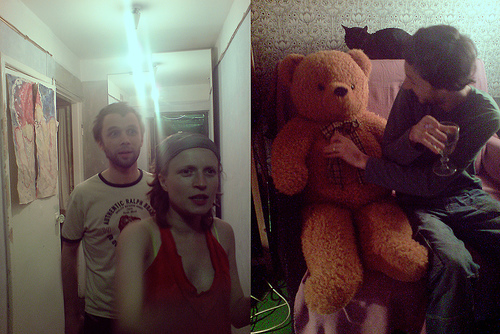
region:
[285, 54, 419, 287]
huge teddy bear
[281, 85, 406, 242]
teddy bear sitting on the furniture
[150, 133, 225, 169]
woman has a bandana on her head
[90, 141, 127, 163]
man has a beard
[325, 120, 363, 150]
bear is wearing a bow tie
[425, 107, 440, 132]
man is holding a cigarette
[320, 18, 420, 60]
cat on the back of the furniture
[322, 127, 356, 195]
man touching the bear's bow tie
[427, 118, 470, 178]
man holding a glass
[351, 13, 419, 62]
cat is black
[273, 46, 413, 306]
large brown fluffy bear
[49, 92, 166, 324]
man wearing a white shirt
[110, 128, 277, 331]
woman wearing red shirt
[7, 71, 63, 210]
painting hanging on the wall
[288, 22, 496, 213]
man sitting next to teddy bear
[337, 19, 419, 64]
small black cat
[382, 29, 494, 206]
man holding a cup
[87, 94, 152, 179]
man with short hair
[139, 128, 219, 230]
woman with grown hair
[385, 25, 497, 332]
man wearing long pants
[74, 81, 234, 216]
These people look surprised.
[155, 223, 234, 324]
The lady has a red tank top.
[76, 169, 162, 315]
The man has a white shirt with black trim.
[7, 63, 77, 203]
This is strange painting.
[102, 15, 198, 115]
The hall light is bright.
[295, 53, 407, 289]
This is a teddy bear.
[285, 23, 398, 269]
The teddy bear is large.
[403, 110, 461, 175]
This man has a wine glass.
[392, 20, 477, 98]
The man has shaggy hair.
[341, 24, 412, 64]
This is a black cat.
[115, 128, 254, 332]
Woman in a red shirt and bandana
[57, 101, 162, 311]
Man in a white shirt with logo on front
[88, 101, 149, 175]
Man with slight scruff facial hair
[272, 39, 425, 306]
Large teddy bear on a couch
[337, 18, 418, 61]
Black cat sitting on top of couch back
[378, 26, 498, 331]
Man touching a teddy bear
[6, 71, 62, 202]
Painted picture hanging on wall in background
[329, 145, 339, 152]
Gold ring on a mans finger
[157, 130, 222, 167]
Blue gray bandana on a woman's head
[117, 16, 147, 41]
Bright light in the background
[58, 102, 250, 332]
A man and woman standing to the left of a teddy.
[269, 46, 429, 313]
A brown teddy bear with a bow tie.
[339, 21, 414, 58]
A black cat behind a man and teddy.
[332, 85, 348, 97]
Black nose on a bear.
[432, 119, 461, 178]
A clear glass in a man's hand.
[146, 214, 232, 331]
A red shirt on a woman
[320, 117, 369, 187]
A plaid bowtie on a bear.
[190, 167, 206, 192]
Nose on a woman's face.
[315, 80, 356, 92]
Black eyes on a teddy bear.